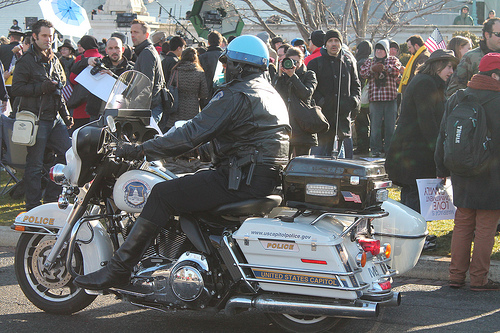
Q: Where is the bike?
A: On the street.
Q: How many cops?
A: 1.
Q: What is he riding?
A: A bike.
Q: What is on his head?
A: Helmet.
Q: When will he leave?
A: Soon.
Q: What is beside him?
A: People.